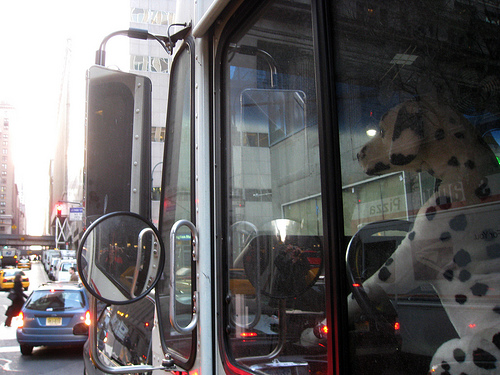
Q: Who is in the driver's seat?
A: Dog.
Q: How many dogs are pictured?
A: One.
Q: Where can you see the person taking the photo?
A: Window's reflection.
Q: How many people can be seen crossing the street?
A: Two.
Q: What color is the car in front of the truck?
A: Blue.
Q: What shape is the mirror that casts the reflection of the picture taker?
A: Circle.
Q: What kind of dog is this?
A: Dalmation.